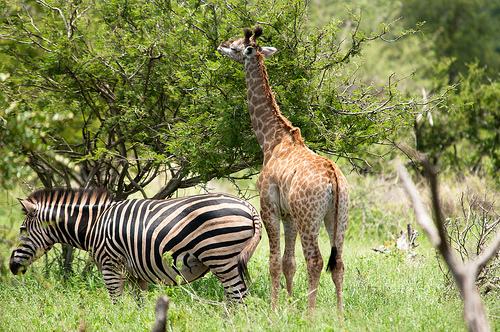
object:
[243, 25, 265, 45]
horns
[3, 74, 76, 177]
wrong picture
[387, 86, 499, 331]
bush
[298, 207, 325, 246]
thigh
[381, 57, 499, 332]
trees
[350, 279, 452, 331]
grass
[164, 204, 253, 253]
stripe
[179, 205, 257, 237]
stripe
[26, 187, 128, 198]
hair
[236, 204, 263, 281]
striped tail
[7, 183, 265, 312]
zebra